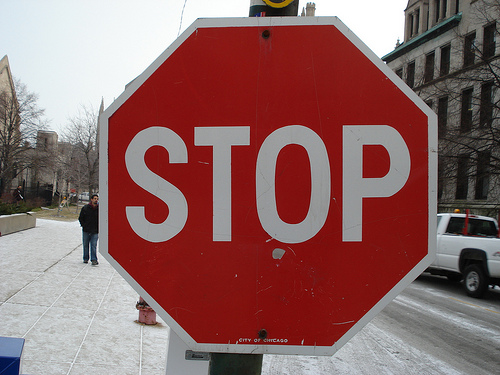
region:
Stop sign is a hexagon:
[97, 12, 439, 357]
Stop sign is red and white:
[92, 14, 441, 359]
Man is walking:
[78, 192, 103, 267]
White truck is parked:
[421, 211, 498, 301]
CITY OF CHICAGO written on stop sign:
[235, 337, 292, 345]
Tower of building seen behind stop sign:
[305, 1, 318, 14]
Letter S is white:
[121, 125, 188, 242]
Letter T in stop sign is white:
[192, 122, 250, 244]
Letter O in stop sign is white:
[255, 122, 328, 240]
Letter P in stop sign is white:
[339, 120, 411, 242]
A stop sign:
[89, 11, 425, 372]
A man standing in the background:
[79, 188, 103, 265]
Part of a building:
[0, 50, 23, 210]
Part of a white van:
[435, 203, 498, 298]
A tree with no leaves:
[64, 107, 103, 196]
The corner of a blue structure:
[1, 330, 24, 374]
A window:
[420, 52, 440, 86]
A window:
[460, 30, 475, 72]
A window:
[452, 86, 482, 135]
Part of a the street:
[362, 285, 494, 374]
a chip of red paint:
[262, 241, 294, 266]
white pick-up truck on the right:
[427, 212, 497, 294]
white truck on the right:
[427, 209, 498, 294]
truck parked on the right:
[423, 205, 498, 300]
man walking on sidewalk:
[76, 186, 103, 266]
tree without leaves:
[0, 75, 46, 219]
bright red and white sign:
[93, 15, 443, 361]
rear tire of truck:
[460, 257, 486, 299]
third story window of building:
[439, 41, 451, 73]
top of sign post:
[245, 0, 301, 17]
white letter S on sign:
[122, 126, 187, 243]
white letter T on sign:
[192, 124, 249, 243]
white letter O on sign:
[255, 123, 331, 243]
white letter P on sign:
[340, 123, 412, 243]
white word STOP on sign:
[121, 122, 409, 242]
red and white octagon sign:
[95, 15, 437, 355]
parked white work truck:
[421, 205, 497, 296]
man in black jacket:
[76, 192, 99, 265]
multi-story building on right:
[376, 0, 497, 215]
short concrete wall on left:
[1, 208, 37, 235]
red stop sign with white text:
[98, 7, 424, 370]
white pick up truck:
[430, 204, 498, 273]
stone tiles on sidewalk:
[2, 282, 104, 353]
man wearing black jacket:
[77, 194, 110, 264]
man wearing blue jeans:
[80, 203, 103, 259]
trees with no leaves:
[0, 77, 46, 212]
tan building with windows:
[415, 21, 487, 121]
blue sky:
[60, 4, 152, 84]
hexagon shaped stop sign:
[78, 10, 448, 366]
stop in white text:
[132, 112, 393, 263]